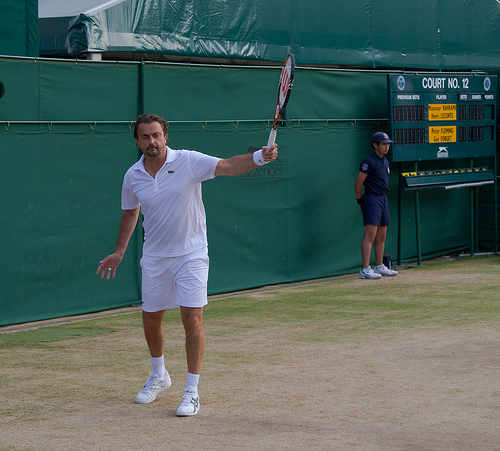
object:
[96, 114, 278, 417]
man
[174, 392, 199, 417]
shoes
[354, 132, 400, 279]
man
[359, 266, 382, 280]
shoes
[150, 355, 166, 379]
socks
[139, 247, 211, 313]
shorts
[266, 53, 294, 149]
racket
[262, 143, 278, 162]
left hand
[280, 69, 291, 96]
w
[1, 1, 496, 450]
court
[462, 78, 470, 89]
12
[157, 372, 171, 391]
heel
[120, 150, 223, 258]
shirt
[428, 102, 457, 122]
sign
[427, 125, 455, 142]
sign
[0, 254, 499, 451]
grass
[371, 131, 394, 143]
hat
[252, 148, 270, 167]
wristband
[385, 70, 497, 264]
score board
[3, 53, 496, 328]
fence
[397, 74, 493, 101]
lettering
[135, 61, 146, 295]
pole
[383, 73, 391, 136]
pole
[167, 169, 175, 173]
logo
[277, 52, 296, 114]
head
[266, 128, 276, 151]
handle